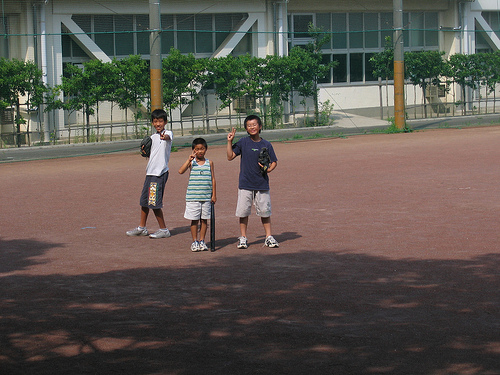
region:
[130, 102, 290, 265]
three boys waving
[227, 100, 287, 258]
a boy in black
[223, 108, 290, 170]
a boy holding a baseball mitt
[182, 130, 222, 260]
a small boy holding a bat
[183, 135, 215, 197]
a small boy wearing a stripped shirt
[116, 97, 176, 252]
a boy holding a mitt and wearing a white shirt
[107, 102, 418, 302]
three boys ready to play baseball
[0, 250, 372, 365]
a dirt park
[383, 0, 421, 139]
a pole in park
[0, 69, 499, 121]
a bunch of trees behind a fence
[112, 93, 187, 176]
boy in white shirt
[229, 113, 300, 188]
boy in blue shirt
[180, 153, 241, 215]
green and white tank top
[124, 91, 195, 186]
boy with black baseball mitt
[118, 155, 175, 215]
gray shorts with white design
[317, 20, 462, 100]
white framed windows on building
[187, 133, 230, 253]
boy holding baseball bat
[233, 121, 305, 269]
boy wearing khaki shorts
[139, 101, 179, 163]
boy has black hair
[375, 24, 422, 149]
gray and yellow post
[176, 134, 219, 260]
a small bowl holding a bat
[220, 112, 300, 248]
a boy holding up two fingers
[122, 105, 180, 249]
a boy in a white shirt holding a black glove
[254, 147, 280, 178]
a black glove tucked under an arm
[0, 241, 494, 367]
the shadow of trees on the roadway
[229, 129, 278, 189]
a navy shirt on a boy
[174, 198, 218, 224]
white shorts on a boy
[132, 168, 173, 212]
grey shorts on a boy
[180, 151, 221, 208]
a striped shirt on a boy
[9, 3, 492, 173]
a building behind three boys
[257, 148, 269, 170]
a dark baseball glove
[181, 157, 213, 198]
a boy's striped tank top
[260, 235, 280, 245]
a boy's tennis shoe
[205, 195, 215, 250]
a dark baseball bat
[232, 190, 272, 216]
boys gray shorts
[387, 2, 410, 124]
a tall gray and yellow pole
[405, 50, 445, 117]
a small green tree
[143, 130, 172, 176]
boys short sleeve shirt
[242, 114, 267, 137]
the head of a boy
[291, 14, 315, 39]
a window of a building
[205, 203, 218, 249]
Dark brown baseball bat.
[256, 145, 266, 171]
Boy in blue shirt holding baseball glove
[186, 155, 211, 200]
Boy wearing a green and white sleeveless shirt.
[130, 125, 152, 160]
Boy in white shirt holding baseball glove.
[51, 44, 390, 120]
Green shrubbery beside building.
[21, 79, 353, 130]
Fence in front of building.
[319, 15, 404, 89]
Windows in building.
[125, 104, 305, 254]
Three boys in front of building.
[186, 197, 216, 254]
Boy in white shorts and sneakers.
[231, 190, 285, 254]
Boy in grey shorts and sneakers.